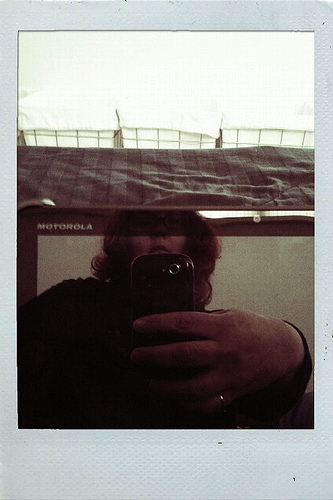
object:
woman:
[16, 207, 313, 428]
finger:
[171, 391, 236, 418]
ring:
[218, 393, 229, 410]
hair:
[90, 209, 222, 313]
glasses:
[129, 212, 188, 230]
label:
[37, 222, 92, 231]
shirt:
[16, 269, 312, 427]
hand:
[132, 307, 307, 419]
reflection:
[17, 206, 312, 432]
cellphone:
[129, 249, 196, 378]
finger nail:
[133, 319, 148, 332]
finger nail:
[131, 349, 148, 364]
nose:
[152, 221, 168, 235]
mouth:
[148, 244, 170, 254]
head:
[90, 208, 221, 308]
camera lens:
[169, 263, 181, 276]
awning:
[16, 143, 316, 208]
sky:
[17, 30, 312, 150]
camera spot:
[253, 215, 261, 224]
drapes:
[17, 144, 313, 207]